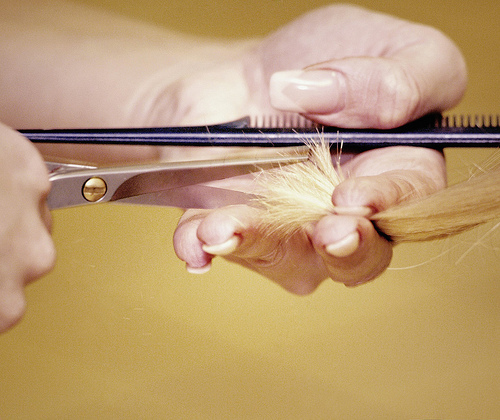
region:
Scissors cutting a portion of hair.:
[42, 151, 307, 207]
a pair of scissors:
[38, 138, 360, 224]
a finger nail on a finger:
[270, 62, 349, 117]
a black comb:
[11, 114, 498, 150]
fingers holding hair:
[169, 150, 439, 313]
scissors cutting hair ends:
[31, 110, 407, 238]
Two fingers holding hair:
[254, 144, 453, 281]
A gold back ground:
[60, 318, 285, 410]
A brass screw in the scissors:
[75, 171, 120, 216]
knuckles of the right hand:
[6, 121, 75, 343]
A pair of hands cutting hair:
[9, 5, 471, 355]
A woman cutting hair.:
[29, 30, 464, 378]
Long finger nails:
[174, 219, 381, 285]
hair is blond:
[259, 170, 468, 240]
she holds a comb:
[57, 123, 493, 152]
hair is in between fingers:
[247, 161, 414, 286]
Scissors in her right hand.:
[42, 151, 314, 220]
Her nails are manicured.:
[164, 212, 376, 287]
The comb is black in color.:
[78, 116, 438, 158]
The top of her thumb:
[257, 45, 457, 104]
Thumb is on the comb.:
[274, 81, 416, 133]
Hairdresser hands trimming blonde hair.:
[9, 4, 499, 339]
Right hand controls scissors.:
[2, 137, 316, 337]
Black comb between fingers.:
[9, 81, 494, 150]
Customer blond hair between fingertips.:
[255, 139, 498, 249]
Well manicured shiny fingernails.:
[257, 60, 360, 124]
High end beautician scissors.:
[44, 150, 291, 212]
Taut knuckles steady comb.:
[339, 40, 443, 130]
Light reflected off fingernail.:
[255, 34, 365, 122]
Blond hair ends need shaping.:
[244, 125, 357, 242]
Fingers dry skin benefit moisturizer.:
[167, 197, 414, 304]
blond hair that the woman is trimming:
[225, 129, 498, 264]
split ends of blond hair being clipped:
[249, 120, 344, 246]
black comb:
[1, 112, 498, 152]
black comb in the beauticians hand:
[10, 112, 499, 157]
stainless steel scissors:
[41, 140, 308, 219]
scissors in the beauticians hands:
[30, 137, 307, 214]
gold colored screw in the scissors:
[72, 173, 107, 203]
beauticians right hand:
[1, 119, 58, 341]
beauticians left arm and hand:
[1, 0, 454, 299]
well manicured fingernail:
[269, 67, 343, 115]